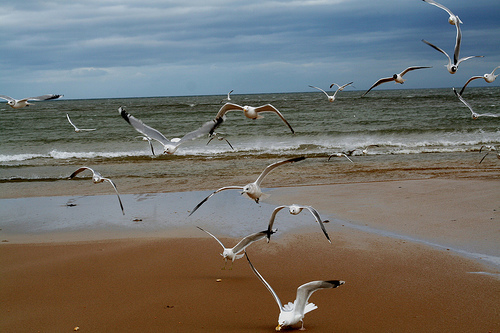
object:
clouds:
[2, 5, 69, 32]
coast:
[0, 86, 500, 333]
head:
[239, 184, 251, 195]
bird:
[186, 157, 308, 219]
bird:
[451, 86, 499, 129]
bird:
[0, 94, 64, 112]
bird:
[265, 205, 331, 244]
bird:
[243, 252, 348, 333]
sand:
[338, 272, 498, 332]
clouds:
[75, 36, 168, 56]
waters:
[0, 87, 500, 196]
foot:
[296, 325, 308, 331]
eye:
[246, 188, 249, 191]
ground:
[0, 155, 500, 331]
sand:
[38, 243, 181, 328]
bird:
[424, 0, 466, 64]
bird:
[118, 106, 223, 155]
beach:
[0, 144, 500, 333]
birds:
[65, 113, 96, 135]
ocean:
[1, 82, 497, 163]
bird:
[194, 229, 276, 266]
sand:
[319, 167, 454, 252]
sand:
[123, 250, 204, 326]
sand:
[279, 248, 315, 273]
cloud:
[67, 66, 109, 79]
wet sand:
[3, 183, 47, 231]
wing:
[253, 103, 295, 134]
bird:
[213, 101, 296, 134]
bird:
[362, 63, 433, 95]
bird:
[308, 81, 354, 103]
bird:
[451, 88, 500, 122]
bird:
[65, 113, 96, 133]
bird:
[68, 167, 124, 215]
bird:
[327, 152, 354, 163]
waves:
[292, 139, 343, 158]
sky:
[0, 0, 500, 102]